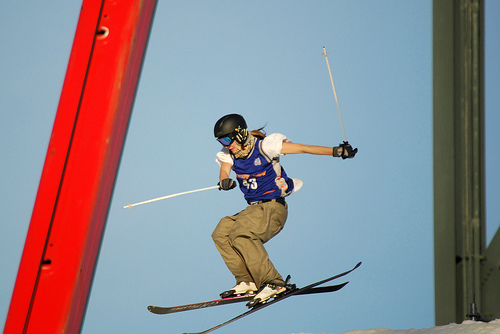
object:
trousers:
[212, 197, 289, 290]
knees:
[212, 216, 260, 252]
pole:
[119, 186, 218, 208]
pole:
[320, 46, 349, 139]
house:
[0, 0, 499, 334]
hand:
[331, 142, 360, 159]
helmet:
[211, 113, 248, 138]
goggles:
[217, 135, 241, 146]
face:
[221, 138, 241, 154]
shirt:
[213, 132, 303, 204]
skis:
[143, 281, 350, 315]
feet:
[245, 284, 288, 309]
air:
[0, 0, 499, 334]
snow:
[341, 319, 500, 333]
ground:
[367, 321, 497, 331]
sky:
[0, 0, 436, 332]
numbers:
[242, 176, 259, 190]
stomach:
[235, 162, 280, 204]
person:
[212, 113, 359, 306]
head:
[213, 113, 252, 155]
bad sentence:
[332, 168, 366, 186]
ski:
[190, 260, 373, 332]